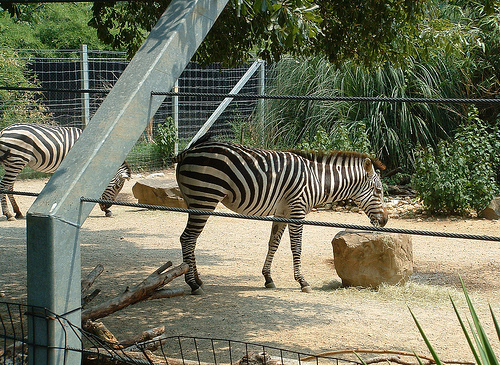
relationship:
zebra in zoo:
[179, 142, 389, 295] [5, 23, 480, 201]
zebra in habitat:
[177, 138, 428, 247] [31, 20, 493, 167]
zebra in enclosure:
[179, 142, 389, 295] [37, 51, 281, 143]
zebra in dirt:
[179, 142, 389, 295] [258, 290, 423, 364]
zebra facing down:
[179, 142, 389, 295] [119, 196, 141, 246]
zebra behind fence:
[179, 142, 389, 295] [172, 76, 272, 139]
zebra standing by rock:
[177, 138, 428, 247] [348, 233, 408, 269]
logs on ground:
[80, 262, 188, 324] [93, 293, 382, 349]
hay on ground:
[413, 269, 499, 312] [93, 293, 382, 349]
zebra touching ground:
[6, 118, 137, 230] [93, 293, 382, 349]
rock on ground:
[348, 233, 408, 269] [93, 293, 382, 349]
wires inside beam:
[64, 78, 477, 110] [30, 149, 131, 342]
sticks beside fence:
[215, 93, 277, 141] [172, 76, 272, 139]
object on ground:
[341, 328, 382, 364] [93, 293, 382, 349]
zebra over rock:
[177, 138, 428, 247] [348, 233, 408, 269]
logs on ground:
[89, 273, 198, 330] [93, 293, 382, 349]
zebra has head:
[177, 138, 428, 247] [367, 169, 406, 234]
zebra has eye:
[177, 138, 428, 247] [370, 184, 382, 198]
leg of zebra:
[288, 217, 316, 316] [177, 138, 428, 247]